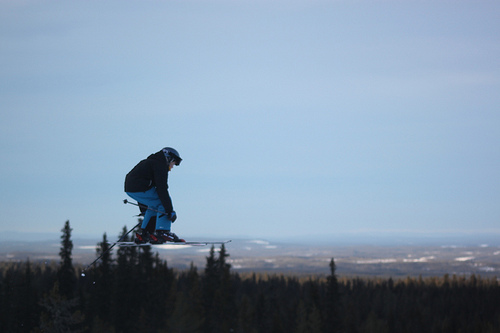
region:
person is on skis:
[80, 153, 202, 267]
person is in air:
[82, 114, 262, 252]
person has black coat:
[117, 155, 191, 193]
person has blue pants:
[140, 191, 185, 225]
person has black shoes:
[140, 223, 177, 253]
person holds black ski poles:
[48, 213, 145, 278]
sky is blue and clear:
[192, 4, 419, 152]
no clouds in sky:
[287, 20, 408, 154]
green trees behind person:
[42, 205, 332, 316]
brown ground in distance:
[242, 233, 452, 277]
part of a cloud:
[376, 195, 413, 232]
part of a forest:
[260, 262, 289, 306]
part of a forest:
[244, 266, 283, 318]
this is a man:
[111, 137, 203, 257]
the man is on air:
[118, 143, 195, 247]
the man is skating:
[121, 140, 191, 244]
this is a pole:
[117, 195, 147, 214]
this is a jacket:
[130, 157, 162, 182]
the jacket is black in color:
[133, 158, 162, 181]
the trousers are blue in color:
[135, 190, 157, 209]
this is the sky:
[282, 21, 455, 188]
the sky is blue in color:
[213, 15, 425, 205]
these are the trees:
[151, 263, 251, 330]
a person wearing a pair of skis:
[88, 146, 243, 256]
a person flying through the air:
[70, 139, 245, 270]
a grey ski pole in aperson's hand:
[115, 198, 182, 219]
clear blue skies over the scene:
[255, 132, 347, 226]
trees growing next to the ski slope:
[237, 273, 396, 320]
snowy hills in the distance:
[213, 231, 290, 261]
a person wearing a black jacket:
[111, 139, 200, 254]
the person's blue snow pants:
[127, 183, 184, 243]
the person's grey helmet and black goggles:
[158, 141, 185, 173]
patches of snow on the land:
[347, 251, 478, 271]